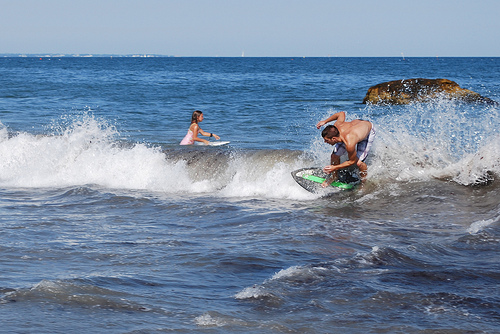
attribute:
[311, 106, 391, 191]
man — surfing, white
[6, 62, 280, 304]
water — white, blue, big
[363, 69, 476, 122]
rock — big, large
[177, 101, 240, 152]
girl — surfing, white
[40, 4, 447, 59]
sky — blue